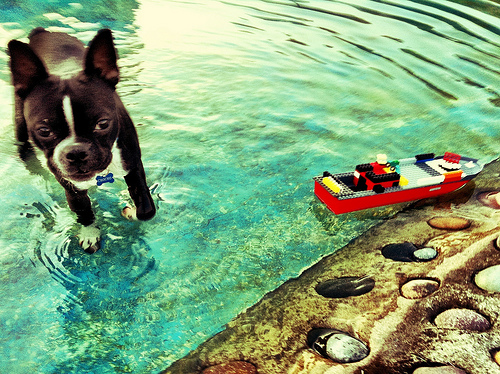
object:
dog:
[5, 25, 159, 257]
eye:
[92, 117, 114, 134]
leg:
[109, 139, 156, 222]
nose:
[65, 151, 89, 167]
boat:
[310, 150, 482, 216]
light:
[199, 37, 254, 76]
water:
[3, 288, 162, 374]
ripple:
[282, 6, 383, 90]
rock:
[314, 275, 375, 298]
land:
[311, 261, 499, 335]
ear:
[82, 28, 120, 92]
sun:
[155, 12, 194, 42]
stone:
[381, 241, 438, 262]